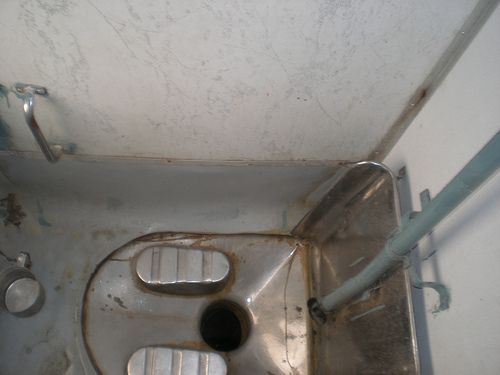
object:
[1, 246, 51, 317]
cup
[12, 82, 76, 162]
metal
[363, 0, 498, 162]
metal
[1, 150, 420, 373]
metal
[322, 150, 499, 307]
pipe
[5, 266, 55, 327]
cup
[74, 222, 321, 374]
toilet seat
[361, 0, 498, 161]
corner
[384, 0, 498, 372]
walls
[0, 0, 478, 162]
walls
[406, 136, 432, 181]
ground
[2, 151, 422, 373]
bathtub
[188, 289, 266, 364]
holes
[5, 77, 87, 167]
handle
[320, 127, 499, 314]
pipe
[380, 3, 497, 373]
wall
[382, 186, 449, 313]
bracket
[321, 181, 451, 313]
pipe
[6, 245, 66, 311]
cup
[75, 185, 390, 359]
toilet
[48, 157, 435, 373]
toilet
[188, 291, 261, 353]
hole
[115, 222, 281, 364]
toilet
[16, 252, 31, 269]
handle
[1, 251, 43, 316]
cup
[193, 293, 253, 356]
drain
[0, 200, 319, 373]
metal floor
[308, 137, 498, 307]
pipe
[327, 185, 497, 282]
pipe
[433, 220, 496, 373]
wall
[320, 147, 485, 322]
pipe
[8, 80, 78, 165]
bar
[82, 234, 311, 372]
toilet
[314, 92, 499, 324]
pipe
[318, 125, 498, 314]
pole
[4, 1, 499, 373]
room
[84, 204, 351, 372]
toilet seat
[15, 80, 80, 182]
handle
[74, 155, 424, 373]
tub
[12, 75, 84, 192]
handle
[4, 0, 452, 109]
wall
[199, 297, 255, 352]
drain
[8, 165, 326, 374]
floor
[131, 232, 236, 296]
foot rest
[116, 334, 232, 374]
foot rest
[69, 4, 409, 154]
wall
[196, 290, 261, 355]
hole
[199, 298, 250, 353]
hole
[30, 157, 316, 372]
ground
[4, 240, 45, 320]
cup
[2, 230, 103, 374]
ground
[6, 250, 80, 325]
cup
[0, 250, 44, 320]
cup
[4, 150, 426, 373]
dirty tub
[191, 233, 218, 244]
stain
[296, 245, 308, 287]
stain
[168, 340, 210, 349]
stain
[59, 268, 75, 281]
stain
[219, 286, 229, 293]
stain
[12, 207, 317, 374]
floor